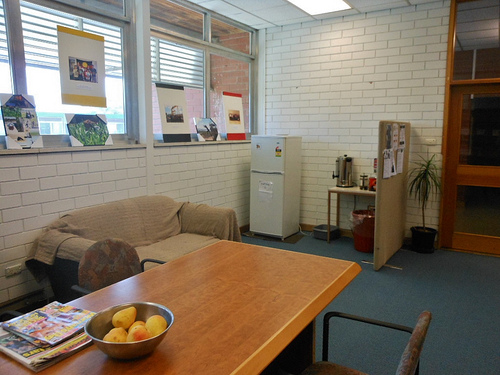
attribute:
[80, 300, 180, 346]
bowl. — silver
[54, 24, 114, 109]
picture — white, yellow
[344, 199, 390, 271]
trash bag — clear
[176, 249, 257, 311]
table — long, wooden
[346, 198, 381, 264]
can — trash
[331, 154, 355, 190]
coffee pot — silver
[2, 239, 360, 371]
table — brown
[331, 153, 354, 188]
coffe pot — coffee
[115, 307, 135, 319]
fruit — yellow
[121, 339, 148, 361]
bowl — metal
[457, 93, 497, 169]
pane — glass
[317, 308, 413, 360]
armrest — metal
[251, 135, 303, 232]
refrigerator — small, white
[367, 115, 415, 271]
partition — light brown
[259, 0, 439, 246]
brick wall — white, brick 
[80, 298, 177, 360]
bowl — metal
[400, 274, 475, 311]
carpet — blue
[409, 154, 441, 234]
plant — house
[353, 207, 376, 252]
trash container — red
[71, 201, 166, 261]
seat — love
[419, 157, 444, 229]
plant — thin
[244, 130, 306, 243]
refrigerator — small, white, tiny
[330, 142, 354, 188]
container — black, silver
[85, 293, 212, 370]
bowl/table — silver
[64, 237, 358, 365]
table — wooden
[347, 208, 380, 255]
pail — red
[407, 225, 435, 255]
pot — black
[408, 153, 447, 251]
plant — green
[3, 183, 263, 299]
sofa — brown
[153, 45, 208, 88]
blinds — open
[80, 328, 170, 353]
bowl — stainless steel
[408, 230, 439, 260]
pot — black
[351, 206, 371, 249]
can — trash, maroon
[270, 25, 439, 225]
wall — white, brick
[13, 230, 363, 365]
table — wooden